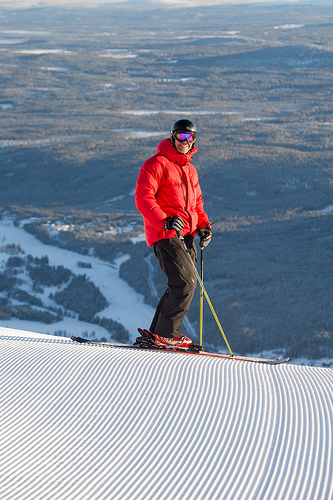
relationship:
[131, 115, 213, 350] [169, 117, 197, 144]
man wearing helmet